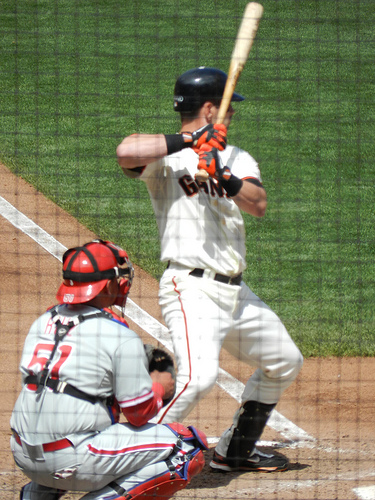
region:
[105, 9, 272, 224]
batter holding bat in air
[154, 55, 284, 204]
batter wearing orange gloves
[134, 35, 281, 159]
batter wearing batting helmet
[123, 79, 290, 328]
batter with white shirt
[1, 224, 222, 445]
catcher behind batter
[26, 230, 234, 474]
catcher wearing red cap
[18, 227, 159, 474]
catcher wearing red belt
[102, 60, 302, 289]
green grass of infield behind batter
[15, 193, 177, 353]
chalk line on baseball diamond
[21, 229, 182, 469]
catcher wearing white shirt with red letters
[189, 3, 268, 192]
wooden baseball bat.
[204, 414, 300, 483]
Cleat on a human foot.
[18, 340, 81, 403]
number 51 on the back of a baseball players shirt.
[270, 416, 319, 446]
section of a line on a baseball field.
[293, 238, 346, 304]
section of green grass on a field.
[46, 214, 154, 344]
baseball player wearing protective gear.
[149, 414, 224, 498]
Protective gear on a baseball player.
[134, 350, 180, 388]
catchers mitt.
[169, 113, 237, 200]
Batting gloves.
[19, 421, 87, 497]
Back side of a catcher.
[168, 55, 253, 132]
hard black baseball helmet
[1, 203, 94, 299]
white chalk line on baseball field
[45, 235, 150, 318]
red umpires helmet with face guard attached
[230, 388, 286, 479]
black shin guard on baseball player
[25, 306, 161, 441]
black straps for umpires chest protector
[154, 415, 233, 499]
hard plastic knee and shin guards for catcher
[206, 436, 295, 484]
black and white Nike baseball cleats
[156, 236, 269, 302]
black beat in white baseball pants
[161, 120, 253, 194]
orange and black batting gloves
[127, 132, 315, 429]
white baseball uniform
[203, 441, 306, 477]
Black baseball cleats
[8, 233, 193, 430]
A catcher with mitt in hand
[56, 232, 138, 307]
A catchers mask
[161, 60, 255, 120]
A black helmet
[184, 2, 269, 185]
A wooden bat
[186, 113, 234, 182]
Red gloves on a batter's hands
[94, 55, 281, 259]
A batter waiting to swing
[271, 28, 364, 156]
A field of green grass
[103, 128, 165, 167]
Light shining on a batter's elbow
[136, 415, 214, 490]
Knee and shin guards on a catcher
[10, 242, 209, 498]
catcher facing pitcher's mound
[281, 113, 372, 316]
manicured green grass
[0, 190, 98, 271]
painted white boundary line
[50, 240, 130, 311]
red catcher's helmet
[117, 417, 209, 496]
red shin and knee pads with blue lining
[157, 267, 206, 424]
white pants with thin white vertical stripe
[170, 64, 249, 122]
black batting helmet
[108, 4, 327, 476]
batter on the mound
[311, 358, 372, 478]
baseball field clay dirt